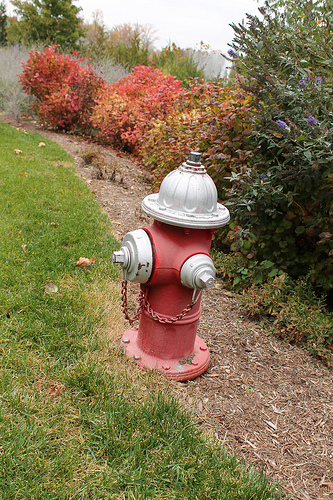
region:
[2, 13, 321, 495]
Exterior, daytime shot.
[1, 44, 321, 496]
Picture, depicting fall scenery and man-made object.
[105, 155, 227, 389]
Red and silver fire hydrant.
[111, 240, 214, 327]
Red chains and silver nozzle caps on fire hydrant.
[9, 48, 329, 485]
Hydrant and vegetation on sloping terrain.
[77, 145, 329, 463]
Wood chip strewn path with hydrant.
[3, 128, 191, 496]
Green grass, alongside path and hydrant.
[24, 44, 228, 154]
Colorful bushes, beside path.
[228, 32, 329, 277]
Large, green bush with purple blooms.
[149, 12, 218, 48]
Milky looking, overcast sky.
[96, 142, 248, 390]
red and silver fire hydrant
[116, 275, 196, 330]
red chains on fire hydrant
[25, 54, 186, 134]
red bushes behind fire hydrant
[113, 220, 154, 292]
silver cap on fire hydrant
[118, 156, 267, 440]
mulch bed in front of bushes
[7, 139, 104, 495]
green grass in front of mulch bed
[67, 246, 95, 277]
dead leaf on grass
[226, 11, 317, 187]
purple flowers on large bush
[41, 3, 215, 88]
tall bushes in distance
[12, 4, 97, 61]
tree behind the red bushes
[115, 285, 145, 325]
red chain hanging from hydrant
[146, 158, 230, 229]
silver dome on hydrant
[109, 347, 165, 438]
grass at base of hydrant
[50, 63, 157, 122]
red leaves on bush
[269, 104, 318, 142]
purple flowers on bush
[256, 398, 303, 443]
wood chips on ground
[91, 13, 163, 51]
tree tops on horizon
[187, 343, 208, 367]
bolts on hydrant base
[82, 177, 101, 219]
edge of green grass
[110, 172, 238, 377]
Fire hydrant on a yard.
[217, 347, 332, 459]
Hay on the ground.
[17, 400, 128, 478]
The grass is green.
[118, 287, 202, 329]
The hydrant has a red chain.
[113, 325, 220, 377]
The bolts are red.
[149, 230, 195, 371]
Body of the hydrant is red.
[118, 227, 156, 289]
The large knob is white.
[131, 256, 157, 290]
Rust on the knob.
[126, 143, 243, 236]
The cap is white.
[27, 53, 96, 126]
Red leaves on the tree.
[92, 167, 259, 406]
red and white fire hydrant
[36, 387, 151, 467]
green grass near fire hydrant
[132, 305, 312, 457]
no grass on this side of fire hydrant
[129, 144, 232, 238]
fire hydrant has white cap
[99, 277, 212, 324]
two red chains on fire hydrant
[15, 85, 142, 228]
path leads away from fire hydrant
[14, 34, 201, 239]
red bushes behind the fire hydrant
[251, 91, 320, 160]
green bush with purple flowers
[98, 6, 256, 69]
white sky in background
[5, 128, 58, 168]
brown leaves on ground